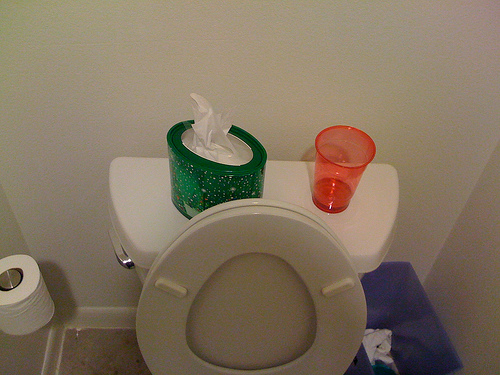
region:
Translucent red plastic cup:
[294, 114, 402, 230]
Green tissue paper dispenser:
[147, 91, 276, 228]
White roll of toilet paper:
[0, 243, 58, 341]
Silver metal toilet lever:
[99, 213, 144, 280]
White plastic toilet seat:
[115, 198, 398, 373]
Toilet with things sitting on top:
[88, 86, 445, 373]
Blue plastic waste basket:
[332, 233, 484, 374]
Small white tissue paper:
[171, 78, 247, 173]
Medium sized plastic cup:
[302, 108, 391, 236]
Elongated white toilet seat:
[148, 198, 397, 373]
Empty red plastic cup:
[315, 127, 367, 212]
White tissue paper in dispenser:
[180, 85, 246, 157]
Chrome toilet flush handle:
[100, 222, 140, 277]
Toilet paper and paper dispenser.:
[0, 255, 53, 335]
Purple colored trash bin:
[362, 261, 467, 371]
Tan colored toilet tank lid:
[115, 153, 395, 245]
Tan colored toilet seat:
[132, 216, 373, 372]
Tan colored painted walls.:
[25, 5, 492, 121]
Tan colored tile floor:
[65, 330, 136, 371]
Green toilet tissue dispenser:
[165, 119, 269, 214]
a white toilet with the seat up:
[90, 150, 412, 372]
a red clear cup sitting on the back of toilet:
[306, 113, 379, 220]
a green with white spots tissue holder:
[155, 103, 280, 221]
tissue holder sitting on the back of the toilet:
[134, 85, 318, 248]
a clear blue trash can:
[349, 235, 474, 373]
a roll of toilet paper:
[1, 251, 56, 335]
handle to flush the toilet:
[85, 217, 140, 275]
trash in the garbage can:
[363, 308, 408, 373]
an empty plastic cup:
[310, 124, 379, 220]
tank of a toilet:
[102, 144, 414, 284]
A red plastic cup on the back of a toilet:
[309, 119, 377, 216]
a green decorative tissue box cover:
[164, 118, 268, 227]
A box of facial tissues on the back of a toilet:
[167, 88, 270, 192]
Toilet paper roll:
[2, 251, 59, 343]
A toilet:
[104, 151, 420, 372]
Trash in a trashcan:
[366, 326, 406, 370]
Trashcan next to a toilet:
[360, 263, 470, 373]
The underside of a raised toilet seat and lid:
[135, 192, 364, 374]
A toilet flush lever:
[104, 220, 135, 272]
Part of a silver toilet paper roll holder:
[0, 267, 23, 293]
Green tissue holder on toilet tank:
[165, 90, 270, 219]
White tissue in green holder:
[163, 90, 268, 220]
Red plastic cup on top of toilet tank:
[312, 124, 377, 213]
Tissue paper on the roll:
[0, 253, 55, 338]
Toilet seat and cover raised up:
[134, 197, 369, 372]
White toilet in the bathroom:
[106, 153, 401, 373]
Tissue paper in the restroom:
[1, 251, 56, 336]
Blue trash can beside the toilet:
[365, 260, 466, 373]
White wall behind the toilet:
[105, 15, 400, 372]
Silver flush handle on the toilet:
[107, 231, 134, 272]